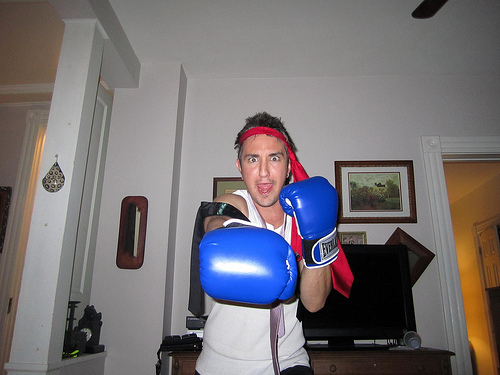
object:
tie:
[186, 201, 250, 319]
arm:
[201, 199, 248, 234]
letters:
[321, 241, 330, 261]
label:
[317, 227, 339, 262]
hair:
[233, 111, 296, 187]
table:
[166, 344, 456, 373]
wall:
[169, 74, 499, 374]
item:
[41, 153, 66, 194]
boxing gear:
[196, 218, 301, 306]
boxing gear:
[280, 176, 341, 270]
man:
[193, 110, 334, 374]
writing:
[319, 230, 342, 260]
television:
[296, 244, 418, 350]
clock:
[76, 303, 108, 355]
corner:
[0, 21, 172, 374]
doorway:
[421, 131, 499, 373]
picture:
[333, 159, 418, 225]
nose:
[258, 159, 269, 178]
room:
[1, 0, 496, 374]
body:
[192, 189, 316, 374]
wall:
[46, 0, 500, 76]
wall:
[63, 64, 183, 375]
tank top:
[191, 187, 333, 375]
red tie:
[236, 126, 354, 299]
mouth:
[253, 180, 276, 197]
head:
[233, 112, 297, 210]